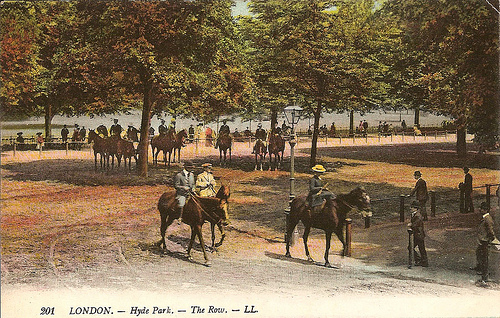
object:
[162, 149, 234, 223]
woman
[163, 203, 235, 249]
horse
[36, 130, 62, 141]
fence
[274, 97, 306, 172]
post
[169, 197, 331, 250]
horses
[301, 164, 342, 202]
hat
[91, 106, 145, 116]
water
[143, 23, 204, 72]
tree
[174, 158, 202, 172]
hat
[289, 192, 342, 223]
type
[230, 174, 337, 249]
carriage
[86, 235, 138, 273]
tracks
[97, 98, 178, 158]
gentleman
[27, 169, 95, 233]
grass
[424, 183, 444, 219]
posts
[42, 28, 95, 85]
colors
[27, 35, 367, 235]
painting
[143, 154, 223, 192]
men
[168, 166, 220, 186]
suits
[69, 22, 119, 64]
leaves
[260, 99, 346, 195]
light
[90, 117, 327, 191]
people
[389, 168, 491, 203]
men